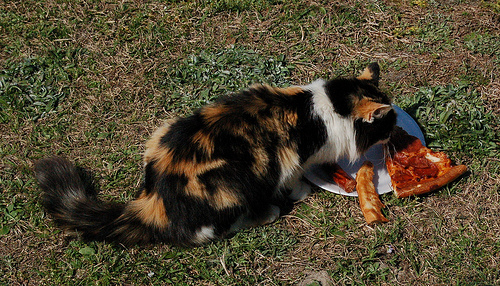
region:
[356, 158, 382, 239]
pizza crust hanging into the grass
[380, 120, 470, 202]
a slice of pepperoni pizza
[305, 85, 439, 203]
a white plate under a slice of pizza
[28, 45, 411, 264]
a cat eating pizza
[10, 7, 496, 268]
short dry grass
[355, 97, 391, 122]
an orange cat ear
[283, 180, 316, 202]
a white cat paw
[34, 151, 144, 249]
a mostly black cat tail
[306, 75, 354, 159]
a white neck on a cat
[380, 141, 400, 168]
white cat whiskers over pizza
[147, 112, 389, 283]
the cat is black and brown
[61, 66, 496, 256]
the cat is black and brown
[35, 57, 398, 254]
One cat in the grass.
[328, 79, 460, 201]
The cat is eating.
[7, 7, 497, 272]
The grass is brown and green.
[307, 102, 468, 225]
Pizza on a plate.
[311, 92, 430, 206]
The plate is white.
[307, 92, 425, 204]
The plate is round.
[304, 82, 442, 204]
The plate is on the grass.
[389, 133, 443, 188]
The pepperonis are red.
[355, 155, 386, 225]
The crust is brown.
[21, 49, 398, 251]
The cat is brown, black and white.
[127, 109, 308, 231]
the cat is orange and black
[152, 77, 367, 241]
the cat is orange and black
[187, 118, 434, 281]
the cat is orange and black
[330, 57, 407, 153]
the head of a cat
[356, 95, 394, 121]
the ear of a cat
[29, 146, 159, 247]
the tail of a cat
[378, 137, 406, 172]
the whiskers of a cat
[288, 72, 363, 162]
the neck of a cat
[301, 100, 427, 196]
a white plate on the ground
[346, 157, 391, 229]
a brown pizza crust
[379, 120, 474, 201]
a piece of pizza on the plate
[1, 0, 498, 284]
a grassy green ground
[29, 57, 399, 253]
a cat on the ground